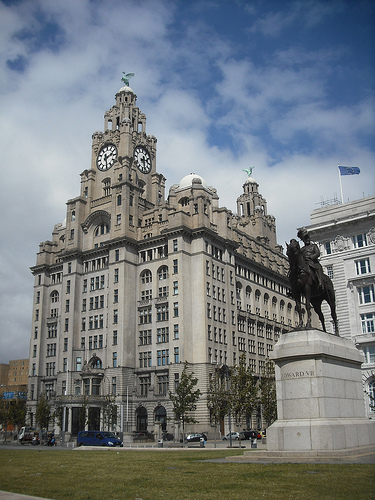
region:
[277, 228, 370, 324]
brown statue in grass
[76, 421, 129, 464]
blue van in front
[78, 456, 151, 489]
green grass by statue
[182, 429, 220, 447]
black car by building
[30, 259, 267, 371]
beige hotel building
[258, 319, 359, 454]
foundation for the brown statue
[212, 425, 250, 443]
gray sedan car by hotel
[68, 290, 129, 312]
window of beige building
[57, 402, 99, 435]
pillars of beige building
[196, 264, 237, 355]
windows of the beige building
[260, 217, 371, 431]
A statue of a person mounted on a horse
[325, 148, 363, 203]
A flag blowing in the wind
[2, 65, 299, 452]
A large building with many windows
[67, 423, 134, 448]
A blue van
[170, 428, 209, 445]
A black car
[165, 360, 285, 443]
A group of trees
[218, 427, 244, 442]
A silver car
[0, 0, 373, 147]
A cloudy blue sky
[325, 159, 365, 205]
The European flag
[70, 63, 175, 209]
A clock tower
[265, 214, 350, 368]
statue of a man on a horse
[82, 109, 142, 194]
large round clock on brown building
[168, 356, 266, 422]
trees on sidewalk near building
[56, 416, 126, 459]
blue van parked on street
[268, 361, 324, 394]
writing on base of statue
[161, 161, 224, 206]
white dome on top of building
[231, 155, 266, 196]
green statue with wings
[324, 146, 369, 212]
blue flag on white pole on building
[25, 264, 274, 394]
many windows on building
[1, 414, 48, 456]
golf cart parked on street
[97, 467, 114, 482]
section of the lawn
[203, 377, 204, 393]
edge of a building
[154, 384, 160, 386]
window of a building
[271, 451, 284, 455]
bottom of a wall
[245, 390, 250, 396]
tip of a tree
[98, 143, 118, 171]
black and white clock in tower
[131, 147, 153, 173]
black and white clock in tower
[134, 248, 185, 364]
side of gray building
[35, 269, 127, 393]
black and white clock in tower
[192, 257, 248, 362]
black and white clock in tower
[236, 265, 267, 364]
black and white clock in tower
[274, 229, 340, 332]
black sculpture of horse and rider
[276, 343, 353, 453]
gray platform under sculpture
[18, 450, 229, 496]
green grass on walk way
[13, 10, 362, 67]
white clouds against blue sky